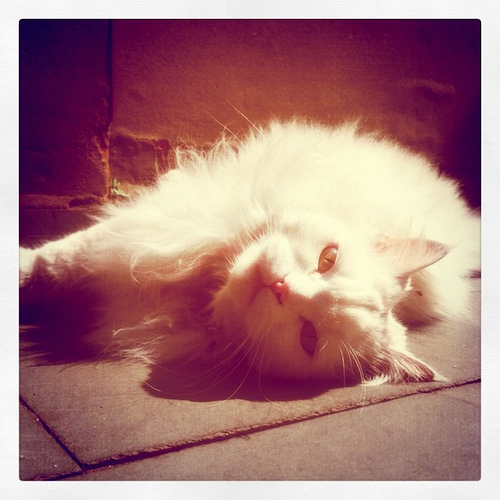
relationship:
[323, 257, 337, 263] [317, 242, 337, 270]
pupil of eye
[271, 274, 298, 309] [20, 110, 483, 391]
nose on cat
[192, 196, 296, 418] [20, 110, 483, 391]
whiskers on cat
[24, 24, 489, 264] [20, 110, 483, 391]
wall behind cat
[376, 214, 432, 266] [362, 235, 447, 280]
hairs in ear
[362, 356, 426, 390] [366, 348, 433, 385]
hairs in ear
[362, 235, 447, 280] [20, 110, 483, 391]
ear of cat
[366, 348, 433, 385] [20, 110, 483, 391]
ear of cat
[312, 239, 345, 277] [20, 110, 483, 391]
eye of cat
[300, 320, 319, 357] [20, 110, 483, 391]
eyes of cat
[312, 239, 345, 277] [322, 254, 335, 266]
eye with slit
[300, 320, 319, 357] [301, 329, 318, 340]
eyes with slit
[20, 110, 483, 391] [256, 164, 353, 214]
cat has fur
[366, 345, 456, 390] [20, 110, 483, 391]
ear of cat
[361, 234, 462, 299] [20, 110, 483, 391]
ear of cat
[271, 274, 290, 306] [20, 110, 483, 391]
nose of cat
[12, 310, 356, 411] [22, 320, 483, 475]
shadow on rug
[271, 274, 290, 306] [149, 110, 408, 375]
nose of cat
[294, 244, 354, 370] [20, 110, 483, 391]
eyes of cat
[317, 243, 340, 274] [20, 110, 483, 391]
eye of cat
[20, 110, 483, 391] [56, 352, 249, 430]
cat laying rug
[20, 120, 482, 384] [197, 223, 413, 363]
cat laying camera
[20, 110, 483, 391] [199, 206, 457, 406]
cat has head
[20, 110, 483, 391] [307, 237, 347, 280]
cat has eye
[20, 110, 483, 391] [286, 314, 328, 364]
cat has eye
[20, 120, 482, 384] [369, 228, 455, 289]
cat has ear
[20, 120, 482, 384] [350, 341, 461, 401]
cat has ear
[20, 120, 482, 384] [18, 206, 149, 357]
cat has legs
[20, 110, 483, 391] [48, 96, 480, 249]
cat has fur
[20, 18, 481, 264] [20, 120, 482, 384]
background behind cat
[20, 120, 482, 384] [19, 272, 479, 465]
cat lying on tile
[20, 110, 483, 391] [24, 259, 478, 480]
cat on pavement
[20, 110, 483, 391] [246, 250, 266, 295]
cat has mouth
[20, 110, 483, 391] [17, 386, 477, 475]
cat on rug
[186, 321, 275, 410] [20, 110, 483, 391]
whiskers of cat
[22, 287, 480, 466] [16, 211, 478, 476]
rug on floor